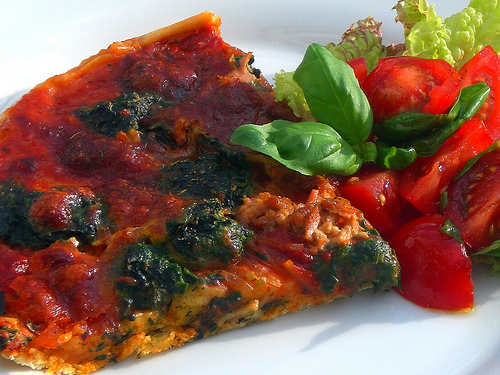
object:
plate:
[0, 0, 499, 375]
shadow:
[198, 269, 499, 353]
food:
[312, 229, 398, 298]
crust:
[0, 11, 251, 126]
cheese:
[0, 9, 370, 337]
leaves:
[290, 41, 375, 147]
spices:
[0, 10, 399, 372]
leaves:
[377, 81, 491, 159]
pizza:
[0, 9, 402, 374]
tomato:
[389, 214, 472, 314]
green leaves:
[230, 119, 362, 180]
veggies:
[289, 43, 374, 147]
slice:
[0, 9, 402, 375]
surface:
[94, 293, 492, 375]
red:
[57, 125, 105, 175]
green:
[124, 240, 196, 294]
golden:
[70, 50, 119, 95]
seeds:
[463, 193, 476, 205]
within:
[452, 160, 496, 215]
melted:
[17, 243, 112, 321]